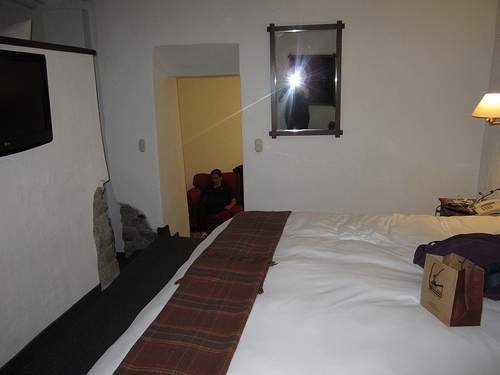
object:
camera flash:
[176, 36, 332, 150]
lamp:
[470, 91, 500, 127]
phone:
[470, 198, 500, 216]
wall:
[0, 32, 122, 373]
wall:
[82, 1, 497, 259]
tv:
[0, 48, 56, 158]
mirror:
[266, 20, 346, 140]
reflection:
[273, 28, 336, 130]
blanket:
[108, 209, 294, 375]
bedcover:
[85, 207, 500, 375]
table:
[436, 196, 490, 217]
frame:
[266, 23, 345, 33]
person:
[232, 163, 245, 209]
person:
[188, 168, 237, 239]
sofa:
[187, 171, 245, 230]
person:
[278, 70, 311, 130]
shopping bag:
[420, 251, 486, 328]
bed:
[83, 207, 498, 375]